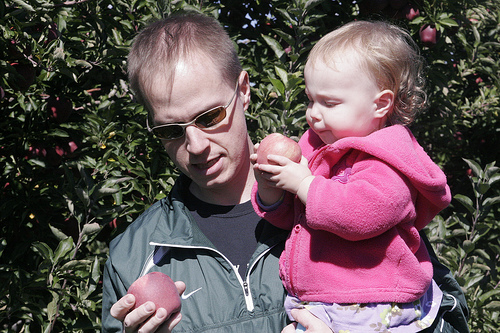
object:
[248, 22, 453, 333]
baby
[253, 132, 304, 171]
apple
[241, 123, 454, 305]
jacket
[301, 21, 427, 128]
blond hair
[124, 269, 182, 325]
apple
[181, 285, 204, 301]
logo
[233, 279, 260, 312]
white zipper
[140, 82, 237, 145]
glasses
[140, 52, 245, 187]
face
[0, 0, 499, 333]
tree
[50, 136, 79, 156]
apple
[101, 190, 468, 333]
shirt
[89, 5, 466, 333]
man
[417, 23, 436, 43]
apples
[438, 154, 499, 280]
plant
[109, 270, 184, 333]
breaker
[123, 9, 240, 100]
blond hair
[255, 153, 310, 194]
hand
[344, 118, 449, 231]
hood